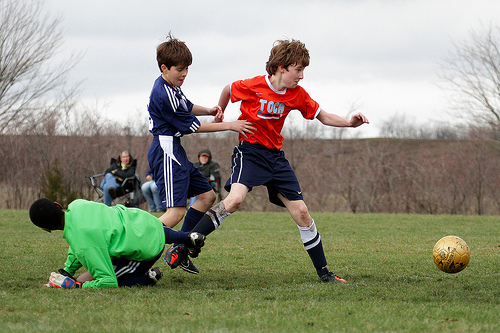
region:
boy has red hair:
[241, 44, 310, 76]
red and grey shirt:
[238, 79, 290, 140]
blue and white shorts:
[228, 142, 296, 197]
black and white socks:
[299, 214, 323, 266]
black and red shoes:
[322, 266, 356, 291]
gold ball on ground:
[432, 234, 466, 279]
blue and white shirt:
[152, 82, 190, 137]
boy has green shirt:
[72, 194, 169, 259]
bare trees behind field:
[0, 52, 495, 186]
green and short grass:
[333, 217, 412, 275]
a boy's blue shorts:
[229, 144, 309, 209]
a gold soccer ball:
[428, 230, 473, 274]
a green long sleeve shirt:
[58, 195, 165, 295]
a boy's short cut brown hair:
[265, 35, 310, 81]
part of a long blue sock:
[182, 205, 200, 231]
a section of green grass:
[312, 209, 497, 234]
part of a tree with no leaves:
[430, 29, 498, 132]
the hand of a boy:
[350, 113, 371, 130]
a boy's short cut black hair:
[27, 198, 67, 229]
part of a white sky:
[100, 3, 263, 30]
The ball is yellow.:
[419, 212, 477, 280]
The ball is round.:
[423, 228, 481, 287]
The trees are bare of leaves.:
[376, 20, 495, 213]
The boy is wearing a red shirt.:
[222, 72, 312, 150]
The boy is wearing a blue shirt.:
[137, 73, 207, 141]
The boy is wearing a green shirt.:
[55, 194, 171, 294]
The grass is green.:
[330, 210, 434, 320]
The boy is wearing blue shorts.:
[223, 138, 313, 205]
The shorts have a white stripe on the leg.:
[222, 139, 251, 191]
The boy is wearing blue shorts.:
[143, 126, 209, 211]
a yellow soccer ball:
[430, 233, 470, 276]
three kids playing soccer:
[26, 29, 371, 291]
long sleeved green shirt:
[61, 196, 166, 290]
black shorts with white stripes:
[113, 245, 166, 287]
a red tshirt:
[227, 73, 326, 151]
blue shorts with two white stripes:
[222, 137, 304, 209]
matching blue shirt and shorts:
[145, 74, 217, 211]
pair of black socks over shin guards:
[192, 199, 332, 279]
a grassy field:
[1, 206, 498, 332]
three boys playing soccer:
[28, 32, 376, 291]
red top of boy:
[231, 72, 321, 150]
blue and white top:
[148, 77, 200, 134]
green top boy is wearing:
[63, 197, 165, 289]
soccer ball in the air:
[433, 235, 470, 272]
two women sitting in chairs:
[88, 147, 224, 209]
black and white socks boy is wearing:
[294, 219, 331, 276]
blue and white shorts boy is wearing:
[148, 134, 189, 210]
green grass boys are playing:
[0, 208, 497, 332]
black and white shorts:
[229, 140, 304, 205]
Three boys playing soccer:
[28, 37, 372, 292]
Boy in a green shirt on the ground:
[23, 196, 205, 290]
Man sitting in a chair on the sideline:
[96, 143, 143, 210]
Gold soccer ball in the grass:
[431, 229, 471, 273]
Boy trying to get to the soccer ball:
[169, 32, 372, 289]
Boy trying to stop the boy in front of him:
[146, 30, 256, 273]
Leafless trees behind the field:
[1, 0, 498, 221]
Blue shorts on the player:
[228, 137, 300, 201]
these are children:
[70, 38, 403, 278]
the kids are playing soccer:
[51, 37, 348, 212]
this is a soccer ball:
[352, 218, 493, 258]